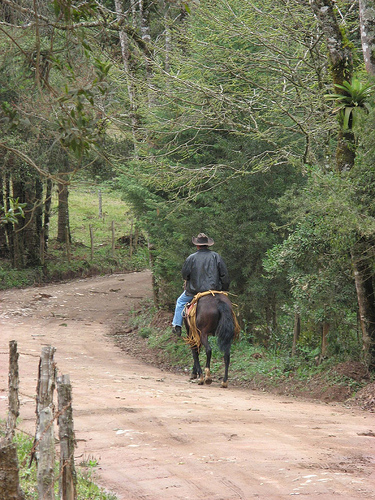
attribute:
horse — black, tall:
[188, 299, 239, 369]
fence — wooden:
[10, 350, 65, 493]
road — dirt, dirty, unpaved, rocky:
[44, 277, 145, 470]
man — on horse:
[171, 230, 237, 298]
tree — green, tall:
[167, 14, 330, 230]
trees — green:
[15, 42, 374, 223]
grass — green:
[73, 193, 122, 229]